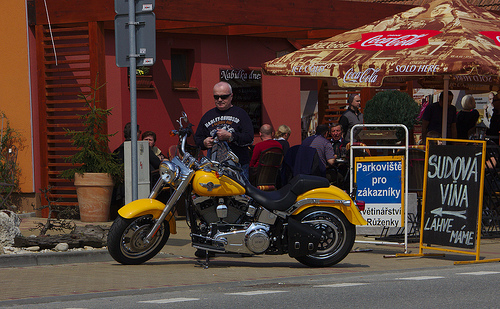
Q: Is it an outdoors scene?
A: Yes, it is outdoors.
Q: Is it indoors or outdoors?
A: It is outdoors.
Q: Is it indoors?
A: No, it is outdoors.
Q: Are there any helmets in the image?
A: No, there are no helmets.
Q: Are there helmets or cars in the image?
A: No, there are no helmets or cars.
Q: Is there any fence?
A: No, there are no fences.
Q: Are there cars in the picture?
A: No, there are no cars.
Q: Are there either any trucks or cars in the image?
A: No, there are no cars or trucks.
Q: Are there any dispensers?
A: No, there are no dispensers.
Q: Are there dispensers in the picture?
A: No, there are no dispensers.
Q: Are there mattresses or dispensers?
A: No, there are no dispensers or mattresses.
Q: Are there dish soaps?
A: No, there are no dish soaps.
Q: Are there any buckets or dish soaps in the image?
A: No, there are no dish soaps or buckets.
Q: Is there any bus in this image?
A: No, there are no buses.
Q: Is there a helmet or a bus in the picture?
A: No, there are no buses or helmets.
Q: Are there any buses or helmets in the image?
A: No, there are no buses or helmets.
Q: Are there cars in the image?
A: No, there are no cars.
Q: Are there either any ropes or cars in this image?
A: No, there are no cars or ropes.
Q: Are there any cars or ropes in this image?
A: No, there are no cars or ropes.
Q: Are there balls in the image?
A: No, there are no balls.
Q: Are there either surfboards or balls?
A: No, there are no balls or surfboards.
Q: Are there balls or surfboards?
A: No, there are no balls or surfboards.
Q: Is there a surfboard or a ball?
A: No, there are no balls or surfboards.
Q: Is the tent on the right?
A: Yes, the tent is on the right of the image.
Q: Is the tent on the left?
A: No, the tent is on the right of the image.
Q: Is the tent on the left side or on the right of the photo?
A: The tent is on the right of the image.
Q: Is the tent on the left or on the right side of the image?
A: The tent is on the right of the image.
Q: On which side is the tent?
A: The tent is on the right of the image.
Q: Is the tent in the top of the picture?
A: Yes, the tent is in the top of the image.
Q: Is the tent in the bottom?
A: No, the tent is in the top of the image.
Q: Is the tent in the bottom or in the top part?
A: The tent is in the top of the image.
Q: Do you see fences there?
A: No, there are no fences.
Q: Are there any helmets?
A: No, there are no helmets.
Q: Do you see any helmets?
A: No, there are no helmets.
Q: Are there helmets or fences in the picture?
A: No, there are no helmets or fences.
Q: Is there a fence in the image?
A: No, there are no fences.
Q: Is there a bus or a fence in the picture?
A: No, there are no fences or buses.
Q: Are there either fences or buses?
A: No, there are no fences or buses.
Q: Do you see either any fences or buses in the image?
A: No, there are no fences or buses.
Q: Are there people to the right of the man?
A: Yes, there are people to the right of the man.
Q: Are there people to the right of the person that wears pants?
A: Yes, there are people to the right of the man.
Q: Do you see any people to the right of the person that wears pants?
A: Yes, there are people to the right of the man.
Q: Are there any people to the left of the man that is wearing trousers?
A: No, the people are to the right of the man.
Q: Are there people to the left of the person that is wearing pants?
A: No, the people are to the right of the man.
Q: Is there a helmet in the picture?
A: No, there are no helmets.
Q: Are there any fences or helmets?
A: No, there are no helmets or fences.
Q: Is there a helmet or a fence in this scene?
A: No, there are no helmets or fences.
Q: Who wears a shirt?
A: The man wears a shirt.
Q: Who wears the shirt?
A: The man wears a shirt.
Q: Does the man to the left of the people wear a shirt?
A: Yes, the man wears a shirt.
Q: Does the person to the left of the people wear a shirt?
A: Yes, the man wears a shirt.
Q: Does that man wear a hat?
A: No, the man wears a shirt.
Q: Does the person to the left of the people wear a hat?
A: No, the man wears a shirt.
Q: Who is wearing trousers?
A: The man is wearing trousers.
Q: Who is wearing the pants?
A: The man is wearing trousers.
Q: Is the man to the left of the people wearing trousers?
A: Yes, the man is wearing trousers.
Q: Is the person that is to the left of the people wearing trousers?
A: Yes, the man is wearing trousers.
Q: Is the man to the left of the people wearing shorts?
A: No, the man is wearing trousers.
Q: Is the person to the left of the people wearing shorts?
A: No, the man is wearing trousers.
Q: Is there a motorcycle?
A: Yes, there is a motorcycle.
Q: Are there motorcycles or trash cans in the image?
A: Yes, there is a motorcycle.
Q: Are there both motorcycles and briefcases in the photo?
A: No, there is a motorcycle but no briefcases.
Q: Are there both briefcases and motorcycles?
A: No, there is a motorcycle but no briefcases.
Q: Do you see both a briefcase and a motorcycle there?
A: No, there is a motorcycle but no briefcases.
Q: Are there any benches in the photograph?
A: No, there are no benches.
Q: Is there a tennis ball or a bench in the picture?
A: No, there are no benches or tennis balls.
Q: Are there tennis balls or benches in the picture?
A: No, there are no benches or tennis balls.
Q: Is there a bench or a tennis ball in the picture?
A: No, there are no benches or tennis balls.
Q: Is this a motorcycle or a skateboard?
A: This is a motorcycle.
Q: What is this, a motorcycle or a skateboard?
A: This is a motorcycle.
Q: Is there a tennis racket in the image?
A: No, there are no rackets.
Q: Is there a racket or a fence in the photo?
A: No, there are no rackets or fences.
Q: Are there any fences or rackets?
A: No, there are no rackets or fences.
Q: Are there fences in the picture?
A: No, there are no fences.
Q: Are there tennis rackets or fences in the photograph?
A: No, there are no fences or tennis rackets.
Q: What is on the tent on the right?
A: The logo is on the tent.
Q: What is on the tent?
A: The logo is on the tent.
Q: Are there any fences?
A: No, there are no fences.